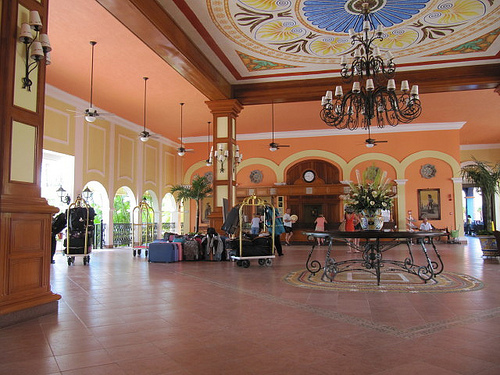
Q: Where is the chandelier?
A: Above the table.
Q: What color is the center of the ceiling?
A: Blue.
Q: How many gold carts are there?
A: Three.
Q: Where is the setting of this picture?
A: Hotel.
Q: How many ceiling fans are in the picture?
A: Six.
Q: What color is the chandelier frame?
A: Black.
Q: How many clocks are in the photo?
A: One.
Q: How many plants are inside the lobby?
A: Three.